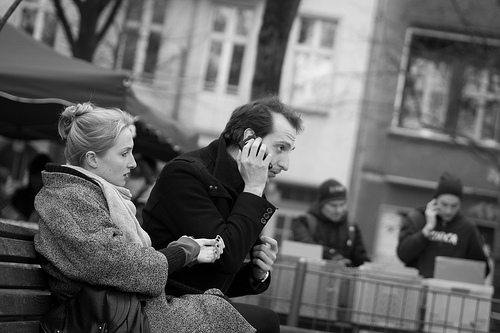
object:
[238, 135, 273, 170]
phone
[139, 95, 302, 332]
man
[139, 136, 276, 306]
jacket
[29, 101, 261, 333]
woman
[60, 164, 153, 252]
scarf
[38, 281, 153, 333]
purse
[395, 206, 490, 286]
man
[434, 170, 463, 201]
hat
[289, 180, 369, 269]
man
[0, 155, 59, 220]
person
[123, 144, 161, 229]
person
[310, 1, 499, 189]
tree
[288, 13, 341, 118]
window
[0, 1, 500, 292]
building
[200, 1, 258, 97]
window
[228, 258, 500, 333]
fence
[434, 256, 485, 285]
laptop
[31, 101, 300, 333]
couple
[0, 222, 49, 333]
bench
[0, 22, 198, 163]
awning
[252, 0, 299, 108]
tree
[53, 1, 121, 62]
trunk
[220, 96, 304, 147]
hair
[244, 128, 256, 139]
ear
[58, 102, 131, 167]
hair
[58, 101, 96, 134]
ponytail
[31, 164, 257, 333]
clothing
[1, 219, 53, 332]
slats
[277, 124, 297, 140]
skin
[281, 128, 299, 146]
forehead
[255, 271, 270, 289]
watch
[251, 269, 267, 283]
wrist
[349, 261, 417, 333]
bin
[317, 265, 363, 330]
part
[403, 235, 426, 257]
part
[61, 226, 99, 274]
part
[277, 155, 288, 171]
nose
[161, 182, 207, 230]
part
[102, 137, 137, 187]
face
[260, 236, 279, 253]
finger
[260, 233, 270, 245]
part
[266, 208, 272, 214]
button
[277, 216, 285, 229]
part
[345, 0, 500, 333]
wall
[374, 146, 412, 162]
part